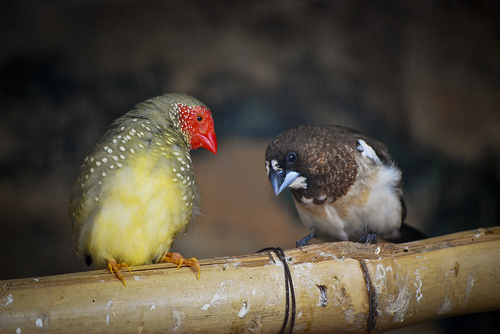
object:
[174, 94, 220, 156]
head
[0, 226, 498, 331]
pole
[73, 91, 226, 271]
bird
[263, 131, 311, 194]
head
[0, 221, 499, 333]
bamboo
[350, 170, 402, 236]
feathers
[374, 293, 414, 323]
white spots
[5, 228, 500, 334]
log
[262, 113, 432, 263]
bird